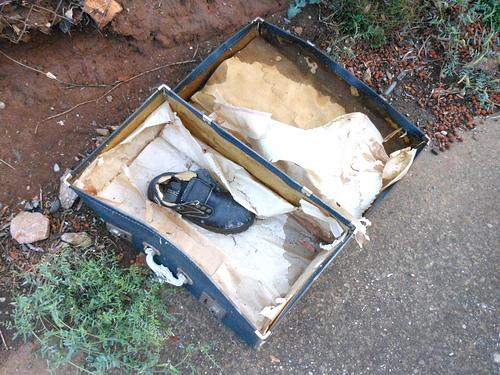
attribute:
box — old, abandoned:
[92, 69, 370, 322]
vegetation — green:
[19, 218, 216, 359]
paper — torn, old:
[138, 169, 349, 280]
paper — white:
[176, 17, 428, 227]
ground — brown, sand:
[8, 3, 496, 373]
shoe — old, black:
[140, 160, 261, 249]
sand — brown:
[3, 2, 315, 214]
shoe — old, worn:
[147, 168, 256, 235]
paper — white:
[307, 128, 399, 201]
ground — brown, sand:
[26, 38, 448, 335]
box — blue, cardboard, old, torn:
[63, 14, 431, 350]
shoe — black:
[124, 131, 284, 313]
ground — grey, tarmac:
[367, 239, 487, 374]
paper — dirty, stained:
[84, 101, 356, 341]